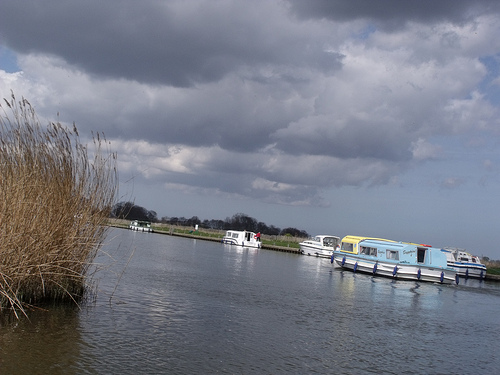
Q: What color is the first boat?
A: Blue.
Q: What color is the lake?
A: Brown.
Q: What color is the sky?
A: Grey.